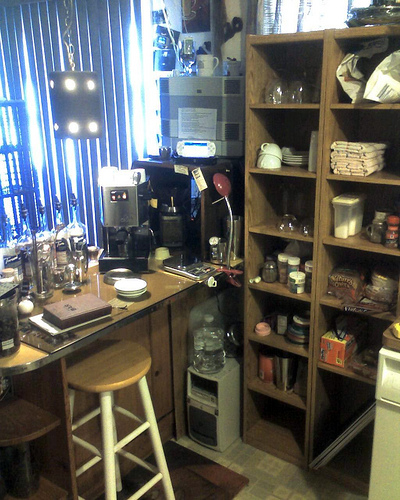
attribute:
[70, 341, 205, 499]
chair — tall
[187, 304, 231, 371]
water bottle — clear, large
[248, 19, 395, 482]
shelf — wooden, full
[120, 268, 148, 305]
plates — white, stacked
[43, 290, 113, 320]
book — red, brown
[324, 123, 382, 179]
towels — stacked, folded, grouped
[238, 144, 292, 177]
cups — white, stacked, small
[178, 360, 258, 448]
pc — white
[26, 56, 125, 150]
lamp — attached, small, hanging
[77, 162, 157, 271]
machine — silver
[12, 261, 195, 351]
table — cluttered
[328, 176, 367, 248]
container — small, plastic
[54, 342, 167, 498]
stool — tan, brown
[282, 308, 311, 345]
bowls — stacked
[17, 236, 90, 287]
bottles — empty